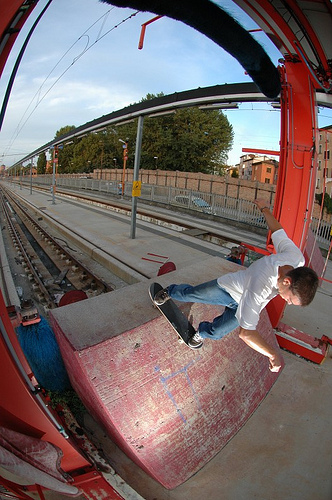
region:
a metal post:
[129, 106, 146, 250]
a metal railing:
[18, 172, 274, 236]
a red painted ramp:
[56, 265, 302, 473]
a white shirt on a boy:
[234, 227, 308, 333]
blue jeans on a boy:
[159, 276, 252, 345]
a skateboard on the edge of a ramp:
[147, 280, 207, 352]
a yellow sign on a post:
[129, 178, 147, 201]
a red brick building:
[245, 155, 277, 188]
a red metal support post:
[257, 92, 312, 309]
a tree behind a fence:
[137, 100, 229, 174]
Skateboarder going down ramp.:
[143, 193, 299, 375]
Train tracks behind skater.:
[2, 181, 134, 313]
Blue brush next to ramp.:
[13, 310, 73, 400]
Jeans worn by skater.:
[165, 278, 251, 343]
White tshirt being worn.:
[215, 228, 310, 331]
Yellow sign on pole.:
[131, 178, 143, 203]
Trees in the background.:
[20, 90, 236, 176]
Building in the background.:
[232, 122, 331, 214]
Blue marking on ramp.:
[149, 354, 220, 435]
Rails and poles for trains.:
[4, 78, 331, 274]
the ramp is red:
[61, 286, 326, 494]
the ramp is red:
[39, 256, 226, 420]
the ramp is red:
[77, 305, 204, 490]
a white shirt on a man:
[215, 225, 308, 334]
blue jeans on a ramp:
[173, 281, 253, 342]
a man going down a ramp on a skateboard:
[138, 216, 323, 370]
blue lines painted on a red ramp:
[152, 346, 214, 434]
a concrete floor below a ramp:
[160, 356, 327, 499]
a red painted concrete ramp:
[44, 269, 319, 462]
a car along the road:
[167, 190, 222, 219]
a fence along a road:
[12, 170, 282, 232]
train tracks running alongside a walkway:
[0, 207, 126, 305]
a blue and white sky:
[4, 3, 320, 185]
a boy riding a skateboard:
[140, 193, 311, 375]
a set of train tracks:
[0, 183, 125, 303]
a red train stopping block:
[48, 243, 293, 489]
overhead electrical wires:
[0, 2, 158, 172]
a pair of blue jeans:
[167, 272, 244, 345]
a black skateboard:
[146, 275, 205, 351]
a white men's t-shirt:
[219, 226, 306, 335]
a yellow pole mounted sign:
[128, 179, 144, 199]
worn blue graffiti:
[151, 356, 218, 431]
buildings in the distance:
[222, 125, 284, 188]